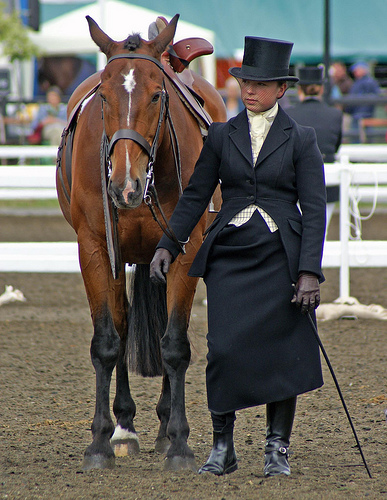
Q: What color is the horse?
A: Brown.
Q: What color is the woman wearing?
A: Black.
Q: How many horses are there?
A: 1.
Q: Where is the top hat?
A: Woman's head.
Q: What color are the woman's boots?
A: Black.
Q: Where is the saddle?
A: Horse's back.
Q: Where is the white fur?
A: Horse's head.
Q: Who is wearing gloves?
A: Woman next to horse.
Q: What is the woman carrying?
A: Stick.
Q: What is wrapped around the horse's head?
A: Reigns.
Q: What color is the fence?
A: White.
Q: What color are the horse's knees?
A: Black.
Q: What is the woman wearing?
A: A long skirt.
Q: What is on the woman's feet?
A: Boots.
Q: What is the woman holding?
A: A riding crop.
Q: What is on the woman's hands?
A: Gloves.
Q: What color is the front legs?
A: Black.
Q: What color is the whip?
A: Black.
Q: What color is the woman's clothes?
A: Black.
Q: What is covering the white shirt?
A: A jacket.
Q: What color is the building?
A: White.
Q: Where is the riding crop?
A: In the woman's hand.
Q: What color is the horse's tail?
A: Black.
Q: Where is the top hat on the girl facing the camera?
A: On head.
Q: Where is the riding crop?
A: Left hand.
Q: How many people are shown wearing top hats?
A: 2.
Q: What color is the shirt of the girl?
A: White.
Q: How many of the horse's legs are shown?
A: 4.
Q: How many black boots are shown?
A: 2.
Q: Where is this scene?
A: A horse jumping competition.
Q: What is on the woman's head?
A: A top hat.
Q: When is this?
A: Daytime.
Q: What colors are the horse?
A: Brown, white, and black.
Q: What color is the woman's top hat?
A: Black.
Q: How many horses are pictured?
A: One.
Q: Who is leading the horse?
A: The woman.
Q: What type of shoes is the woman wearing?
A: Boots.